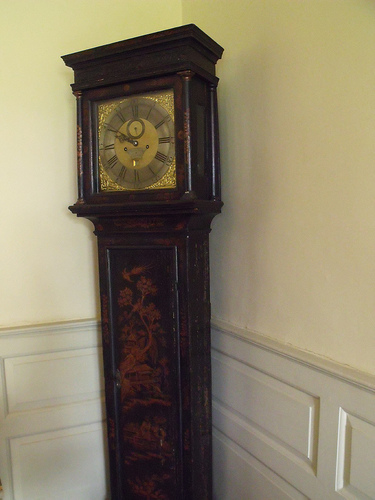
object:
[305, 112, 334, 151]
ground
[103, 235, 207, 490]
wood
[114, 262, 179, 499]
carving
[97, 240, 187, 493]
door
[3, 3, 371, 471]
walls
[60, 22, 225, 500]
grandfather clock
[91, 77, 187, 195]
clock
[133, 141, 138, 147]
center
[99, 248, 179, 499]
pattern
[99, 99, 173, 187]
numerals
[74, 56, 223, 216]
wood base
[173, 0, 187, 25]
corner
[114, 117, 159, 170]
gold circle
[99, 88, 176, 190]
gold face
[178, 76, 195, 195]
column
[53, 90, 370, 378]
wallwood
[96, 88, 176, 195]
driveway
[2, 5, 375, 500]
room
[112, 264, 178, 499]
design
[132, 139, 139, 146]
middle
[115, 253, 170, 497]
image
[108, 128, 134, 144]
hands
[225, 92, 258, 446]
shadow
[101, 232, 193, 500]
decor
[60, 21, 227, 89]
top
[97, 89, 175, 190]
face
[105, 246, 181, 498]
decorative portion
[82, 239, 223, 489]
corner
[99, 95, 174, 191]
roman numerals